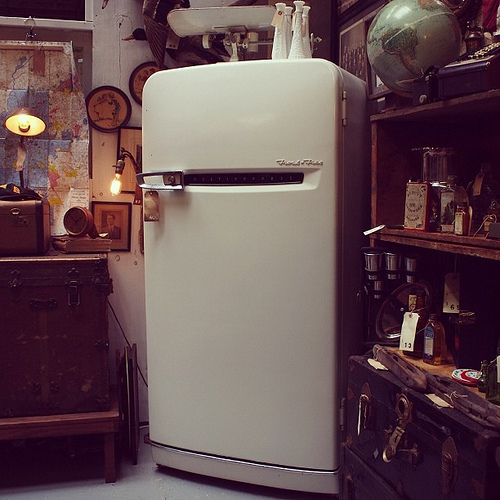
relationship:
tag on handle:
[142, 190, 159, 221] [135, 171, 184, 192]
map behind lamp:
[5, 37, 95, 248] [2, 99, 47, 202]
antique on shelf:
[404, 179, 431, 233] [348, 60, 498, 472]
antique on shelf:
[400, 177, 431, 227] [340, 240, 497, 390]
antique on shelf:
[404, 179, 431, 233] [377, 91, 499, 108]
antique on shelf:
[370, 345, 430, 392] [368, 243, 498, 394]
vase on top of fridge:
[269, 1, 288, 58] [135, 57, 370, 495]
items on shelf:
[384, 130, 498, 241] [342, 99, 498, 494]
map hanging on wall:
[0, 40, 90, 236] [0, 0, 333, 427]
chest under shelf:
[334, 347, 499, 497] [365, 95, 498, 260]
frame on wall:
[90, 200, 131, 254] [83, 0, 155, 437]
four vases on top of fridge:
[261, 0, 319, 61] [136, 55, 375, 498]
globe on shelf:
[365, 3, 464, 98] [366, 0, 497, 422]